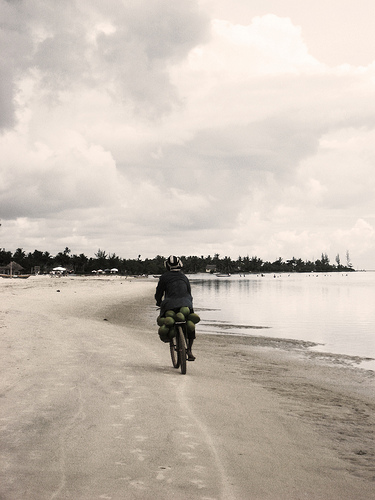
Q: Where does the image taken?
A: Beach.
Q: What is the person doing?
A: Riding bike.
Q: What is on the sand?
A: Footprints.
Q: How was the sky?
A: Cloudy.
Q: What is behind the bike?
A: Dark trees.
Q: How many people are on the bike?
A: One.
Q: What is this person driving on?
A: The beach.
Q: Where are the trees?
A: Behind the buildings.